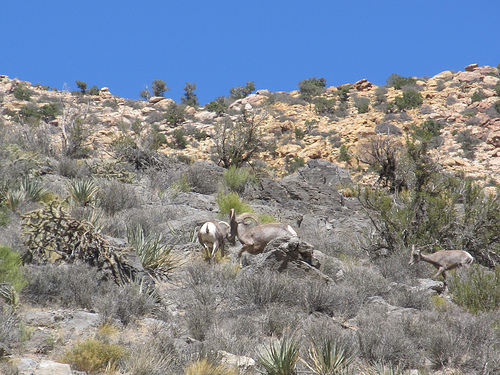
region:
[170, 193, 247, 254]
brown and white bighorn sheep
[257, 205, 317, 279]
brown and white bighorn sheep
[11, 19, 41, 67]
white clouds in blue sky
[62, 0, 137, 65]
white clouds in blue sky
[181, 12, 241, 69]
white clouds in blue sky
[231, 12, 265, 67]
white clouds in blue sky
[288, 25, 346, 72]
white clouds in blue sky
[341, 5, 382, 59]
white clouds in blue sky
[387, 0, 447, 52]
white clouds in blue sky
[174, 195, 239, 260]
bighorn sheep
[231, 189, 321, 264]
bighorn sheep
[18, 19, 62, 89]
white clouds in blue sky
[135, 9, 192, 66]
white clouds in blue sky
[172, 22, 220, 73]
white clouds in blue sky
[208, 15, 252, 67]
white clouds in blue sky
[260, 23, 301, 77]
white clouds in blue sky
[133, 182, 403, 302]
These are animals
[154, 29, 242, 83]
There are no clouds in the sky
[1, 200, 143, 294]
This is an old tree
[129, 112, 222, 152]
This is a mountain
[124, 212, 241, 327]
The grass is parched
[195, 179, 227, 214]
This is a patch of grass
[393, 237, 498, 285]
This is a gazelle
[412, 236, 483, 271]
The animal is brown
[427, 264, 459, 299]
These are legs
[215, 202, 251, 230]
These are horns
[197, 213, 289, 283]
two mountain goats on hill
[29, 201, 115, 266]
really dry prickly plant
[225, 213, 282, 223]
mountain goat has curved horns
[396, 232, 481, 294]
animal with wavy horns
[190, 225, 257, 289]
butt of animal walking away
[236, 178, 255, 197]
living green small bush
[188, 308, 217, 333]
really dry gray bush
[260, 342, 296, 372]
plant with pointy leaves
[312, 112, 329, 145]
orange rocky area above goat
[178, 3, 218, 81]
sky is vibrant and clear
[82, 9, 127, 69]
white clouds in blue sky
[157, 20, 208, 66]
white clouds in blue sky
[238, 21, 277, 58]
white clouds in blue sky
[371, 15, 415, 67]
white clouds in blue sky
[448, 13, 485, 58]
white clouds in blue sky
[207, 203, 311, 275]
gray and white bighorn sheep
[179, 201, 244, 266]
sheep